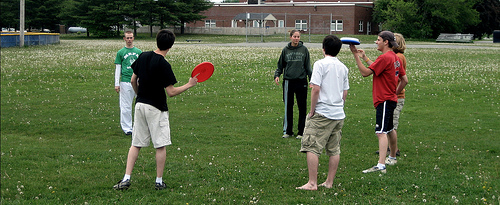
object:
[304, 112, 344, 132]
hip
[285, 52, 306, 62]
logo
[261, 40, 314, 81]
hoodie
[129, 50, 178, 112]
shirt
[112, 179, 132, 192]
foot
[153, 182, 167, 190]
foot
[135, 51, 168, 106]
back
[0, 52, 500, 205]
field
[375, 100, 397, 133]
black shorts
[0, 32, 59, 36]
stripe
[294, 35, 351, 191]
boy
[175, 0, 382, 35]
building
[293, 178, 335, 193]
feet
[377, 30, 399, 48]
cap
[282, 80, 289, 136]
stripe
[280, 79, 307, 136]
sweatpants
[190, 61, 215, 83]
frisbee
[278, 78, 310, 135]
pants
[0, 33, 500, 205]
grass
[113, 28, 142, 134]
kid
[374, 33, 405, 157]
kid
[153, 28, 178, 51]
hair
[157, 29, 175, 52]
head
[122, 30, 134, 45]
head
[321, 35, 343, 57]
head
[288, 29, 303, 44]
head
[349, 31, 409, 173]
boy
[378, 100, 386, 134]
stripe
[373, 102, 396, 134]
shorts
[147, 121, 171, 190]
leg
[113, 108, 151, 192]
leg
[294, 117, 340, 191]
leg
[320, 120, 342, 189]
leg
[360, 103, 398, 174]
leg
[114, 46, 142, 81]
green shirt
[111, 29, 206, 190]
boy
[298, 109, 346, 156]
shorts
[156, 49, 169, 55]
neck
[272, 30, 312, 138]
girl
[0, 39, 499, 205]
flowers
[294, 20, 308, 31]
window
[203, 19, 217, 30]
window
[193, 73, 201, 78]
finger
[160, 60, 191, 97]
arm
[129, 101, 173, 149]
shorts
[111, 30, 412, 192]
group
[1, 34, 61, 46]
fence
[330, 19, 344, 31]
window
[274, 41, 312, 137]
clothes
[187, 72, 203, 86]
hand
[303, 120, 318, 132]
pocket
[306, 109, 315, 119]
hand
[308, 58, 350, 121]
shirt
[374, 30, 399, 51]
head